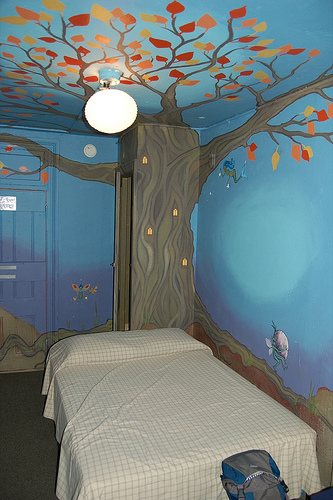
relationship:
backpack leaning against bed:
[220, 449, 291, 500] [42, 327, 321, 500]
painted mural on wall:
[2, 125, 331, 456] [0, 125, 333, 487]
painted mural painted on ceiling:
[0, 0, 332, 488] [0, 1, 331, 131]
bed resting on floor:
[42, 327, 321, 500] [2, 369, 332, 497]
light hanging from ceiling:
[84, 88, 139, 134] [0, 1, 331, 131]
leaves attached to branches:
[10, 3, 310, 81] [10, 50, 333, 183]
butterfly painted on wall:
[69, 281, 99, 304] [0, 125, 333, 487]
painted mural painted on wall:
[2, 125, 331, 456] [0, 125, 333, 487]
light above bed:
[84, 88, 139, 134] [42, 327, 321, 500]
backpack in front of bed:
[220, 449, 291, 500] [42, 327, 321, 500]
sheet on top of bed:
[41, 327, 329, 499] [42, 327, 321, 500]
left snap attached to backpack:
[279, 479, 288, 493] [220, 449, 291, 500]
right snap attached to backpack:
[238, 484, 246, 500] [220, 449, 291, 500]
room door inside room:
[0, 130, 66, 375] [1, 1, 333, 497]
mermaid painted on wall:
[222, 158, 249, 186] [0, 125, 333, 487]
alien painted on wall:
[265, 321, 290, 373] [0, 125, 333, 487]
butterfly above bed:
[69, 281, 99, 304] [42, 327, 321, 500]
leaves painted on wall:
[10, 3, 310, 81] [0, 125, 333, 487]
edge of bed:
[86, 433, 322, 498] [42, 327, 321, 500]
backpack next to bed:
[220, 449, 291, 500] [42, 327, 321, 500]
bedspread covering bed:
[41, 327, 329, 499] [42, 327, 321, 500]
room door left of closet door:
[0, 130, 66, 375] [113, 163, 135, 357]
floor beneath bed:
[2, 369, 332, 497] [42, 327, 321, 500]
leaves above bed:
[10, 3, 310, 81] [42, 327, 321, 500]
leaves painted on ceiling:
[10, 3, 310, 81] [0, 1, 331, 131]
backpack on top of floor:
[220, 449, 291, 500] [2, 369, 332, 497]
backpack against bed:
[220, 449, 291, 500] [42, 327, 321, 500]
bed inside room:
[42, 327, 321, 500] [1, 1, 333, 497]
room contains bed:
[1, 1, 333, 497] [42, 327, 321, 500]